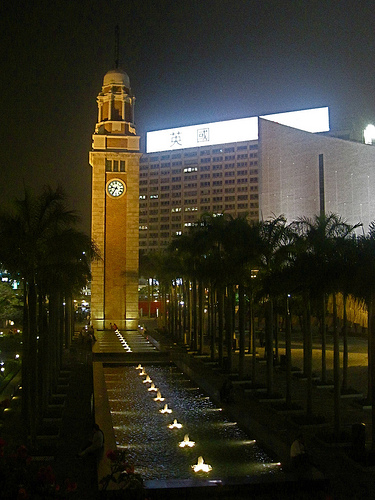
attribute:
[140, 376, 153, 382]
candle — lit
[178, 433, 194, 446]
candle — lit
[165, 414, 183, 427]
candle — lit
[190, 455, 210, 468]
candle — lit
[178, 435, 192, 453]
candle — lit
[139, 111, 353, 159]
billboard — lighted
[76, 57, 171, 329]
building — tall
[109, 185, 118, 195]
hands — black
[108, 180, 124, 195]
numbers — black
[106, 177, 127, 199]
clock — white 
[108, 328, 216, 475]
candles — lit 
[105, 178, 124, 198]
clock face — white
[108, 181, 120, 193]
markings — black number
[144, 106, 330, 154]
digital sign — large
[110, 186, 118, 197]
hand — black 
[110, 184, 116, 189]
hand — black 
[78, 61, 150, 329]
tower — narrow, tall 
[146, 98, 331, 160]
sign — large 